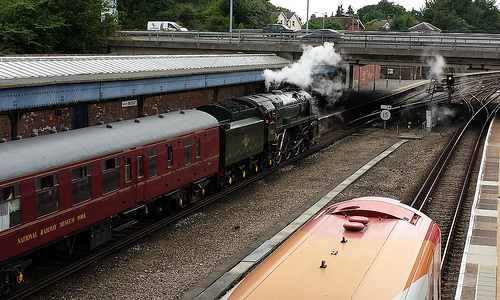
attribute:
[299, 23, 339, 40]
car — coal, train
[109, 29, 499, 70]
bridge — concrete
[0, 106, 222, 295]
train car — red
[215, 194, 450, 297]
train — orange, red, white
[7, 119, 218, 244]
car — red, passenger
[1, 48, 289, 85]
roof — metal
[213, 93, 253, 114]
coal — black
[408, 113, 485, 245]
slats — wooden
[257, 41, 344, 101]
smoke — white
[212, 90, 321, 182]
train — green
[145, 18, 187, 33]
van — white, panel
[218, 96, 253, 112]
coal — black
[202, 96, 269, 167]
car — green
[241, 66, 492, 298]
tracks — railroad